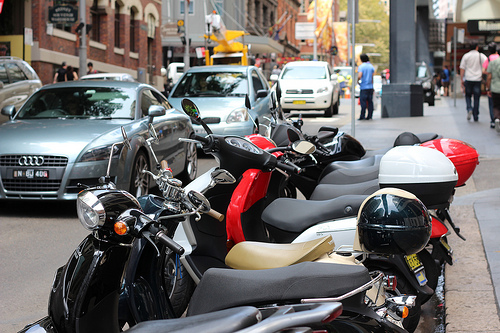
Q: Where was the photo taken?
A: It was taken at the road.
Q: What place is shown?
A: It is a road.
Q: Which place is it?
A: It is a road.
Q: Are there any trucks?
A: No, there are no trucks.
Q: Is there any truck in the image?
A: No, there are no trucks.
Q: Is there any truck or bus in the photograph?
A: No, there are no trucks or buses.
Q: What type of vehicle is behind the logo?
A: The vehicle is a car.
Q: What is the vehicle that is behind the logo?
A: The vehicle is a car.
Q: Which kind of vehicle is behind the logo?
A: The vehicle is a car.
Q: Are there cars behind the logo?
A: Yes, there is a car behind the logo.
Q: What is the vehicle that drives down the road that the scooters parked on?
A: The vehicle is a car.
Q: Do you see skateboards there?
A: No, there are no skateboards.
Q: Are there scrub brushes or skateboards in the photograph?
A: No, there are no skateboards or scrub brushes.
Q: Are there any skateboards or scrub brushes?
A: No, there are no skateboards or scrub brushes.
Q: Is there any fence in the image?
A: No, there are no fences.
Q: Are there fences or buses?
A: No, there are no fences or buses.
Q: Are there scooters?
A: Yes, there are scooters.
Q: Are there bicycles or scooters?
A: Yes, there are scooters.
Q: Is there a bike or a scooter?
A: Yes, there are scooters.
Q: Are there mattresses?
A: No, there are no mattresses.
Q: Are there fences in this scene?
A: No, there are no fences.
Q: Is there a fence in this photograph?
A: No, there are no fences.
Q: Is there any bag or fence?
A: No, there are no fences or bags.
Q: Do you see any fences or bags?
A: No, there are no fences or bags.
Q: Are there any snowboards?
A: No, there are no snowboards.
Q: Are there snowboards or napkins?
A: No, there are no snowboards or napkins.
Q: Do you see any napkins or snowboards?
A: No, there are no snowboards or napkins.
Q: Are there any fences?
A: No, there are no fences.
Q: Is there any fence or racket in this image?
A: No, there are no fences or rackets.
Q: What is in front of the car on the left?
A: The logo is in front of the car.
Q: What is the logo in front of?
A: The logo is in front of the car.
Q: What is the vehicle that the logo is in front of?
A: The vehicle is a car.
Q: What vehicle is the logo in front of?
A: The logo is in front of the car.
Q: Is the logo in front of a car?
A: Yes, the logo is in front of a car.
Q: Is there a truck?
A: No, there are no trucks.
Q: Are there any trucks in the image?
A: No, there are no trucks.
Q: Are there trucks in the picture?
A: No, there are no trucks.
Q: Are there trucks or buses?
A: No, there are no trucks or buses.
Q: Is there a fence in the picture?
A: No, there are no fences.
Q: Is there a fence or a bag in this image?
A: No, there are no fences or bags.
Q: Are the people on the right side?
A: Yes, the people are on the right of the image.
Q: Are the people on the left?
A: No, the people are on the right of the image.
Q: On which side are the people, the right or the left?
A: The people are on the right of the image.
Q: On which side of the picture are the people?
A: The people are on the right of the image.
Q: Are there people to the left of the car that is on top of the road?
A: No, the people are to the right of the car.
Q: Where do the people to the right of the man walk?
A: The people walk on the sidewalk.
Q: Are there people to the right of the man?
A: Yes, there are people to the right of the man.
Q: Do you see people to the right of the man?
A: Yes, there are people to the right of the man.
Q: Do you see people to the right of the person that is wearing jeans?
A: Yes, there are people to the right of the man.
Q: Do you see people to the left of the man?
A: No, the people are to the right of the man.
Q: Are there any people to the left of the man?
A: No, the people are to the right of the man.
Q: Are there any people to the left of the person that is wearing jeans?
A: No, the people are to the right of the man.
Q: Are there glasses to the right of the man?
A: No, there are people to the right of the man.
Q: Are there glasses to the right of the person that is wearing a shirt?
A: No, there are people to the right of the man.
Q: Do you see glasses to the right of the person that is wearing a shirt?
A: No, there are people to the right of the man.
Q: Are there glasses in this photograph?
A: No, there are no glasses.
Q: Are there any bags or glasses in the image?
A: No, there are no glasses or bags.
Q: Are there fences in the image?
A: No, there are no fences.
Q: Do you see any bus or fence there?
A: No, there are no fences or buses.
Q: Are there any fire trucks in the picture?
A: No, there are no fire trucks.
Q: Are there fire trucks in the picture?
A: No, there are no fire trucks.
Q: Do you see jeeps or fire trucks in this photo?
A: No, there are no fire trucks or jeeps.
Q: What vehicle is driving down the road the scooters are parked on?
A: The vehicle is a car.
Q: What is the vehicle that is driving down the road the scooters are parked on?
A: The vehicle is a car.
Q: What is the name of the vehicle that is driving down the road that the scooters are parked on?
A: The vehicle is a car.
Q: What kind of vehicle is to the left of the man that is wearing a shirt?
A: The vehicle is a car.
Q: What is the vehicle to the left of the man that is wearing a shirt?
A: The vehicle is a car.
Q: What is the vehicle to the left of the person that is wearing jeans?
A: The vehicle is a car.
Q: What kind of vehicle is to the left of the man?
A: The vehicle is a car.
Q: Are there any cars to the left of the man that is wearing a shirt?
A: Yes, there is a car to the left of the man.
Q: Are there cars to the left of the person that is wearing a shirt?
A: Yes, there is a car to the left of the man.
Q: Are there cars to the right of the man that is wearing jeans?
A: No, the car is to the left of the man.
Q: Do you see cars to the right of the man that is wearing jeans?
A: No, the car is to the left of the man.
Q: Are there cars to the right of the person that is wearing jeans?
A: No, the car is to the left of the man.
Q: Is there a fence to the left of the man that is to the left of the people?
A: No, there is a car to the left of the man.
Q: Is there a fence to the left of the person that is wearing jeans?
A: No, there is a car to the left of the man.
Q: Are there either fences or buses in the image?
A: No, there are no fences or buses.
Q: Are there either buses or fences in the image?
A: No, there are no fences or buses.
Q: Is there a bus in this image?
A: No, there are no buses.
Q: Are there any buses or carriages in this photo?
A: No, there are no buses or carriages.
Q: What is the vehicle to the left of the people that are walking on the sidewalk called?
A: The vehicle is a car.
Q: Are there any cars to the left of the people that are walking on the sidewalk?
A: Yes, there is a car to the left of the people.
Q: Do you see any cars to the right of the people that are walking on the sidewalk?
A: No, the car is to the left of the people.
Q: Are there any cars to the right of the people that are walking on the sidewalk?
A: No, the car is to the left of the people.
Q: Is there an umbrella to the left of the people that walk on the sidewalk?
A: No, there is a car to the left of the people.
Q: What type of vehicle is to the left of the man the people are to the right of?
A: The vehicle is a car.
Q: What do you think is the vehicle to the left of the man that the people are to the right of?
A: The vehicle is a car.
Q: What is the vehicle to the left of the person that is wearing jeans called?
A: The vehicle is a car.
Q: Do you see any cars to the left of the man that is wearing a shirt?
A: Yes, there is a car to the left of the man.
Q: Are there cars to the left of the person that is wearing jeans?
A: Yes, there is a car to the left of the man.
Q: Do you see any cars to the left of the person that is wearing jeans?
A: Yes, there is a car to the left of the man.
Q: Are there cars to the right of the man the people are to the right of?
A: No, the car is to the left of the man.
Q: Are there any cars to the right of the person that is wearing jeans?
A: No, the car is to the left of the man.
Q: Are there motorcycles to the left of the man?
A: No, there is a car to the left of the man.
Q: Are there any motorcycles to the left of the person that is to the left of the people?
A: No, there is a car to the left of the man.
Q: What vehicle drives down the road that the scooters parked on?
A: The vehicle is a car.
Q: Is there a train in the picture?
A: No, there are no trains.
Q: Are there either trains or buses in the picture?
A: No, there are no trains or buses.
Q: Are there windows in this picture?
A: Yes, there is a window.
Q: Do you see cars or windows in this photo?
A: Yes, there is a window.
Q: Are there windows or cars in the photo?
A: Yes, there is a window.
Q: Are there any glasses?
A: No, there are no glasses.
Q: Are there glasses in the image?
A: No, there are no glasses.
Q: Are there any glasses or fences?
A: No, there are no glasses or fences.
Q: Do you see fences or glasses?
A: No, there are no glasses or fences.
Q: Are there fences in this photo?
A: No, there are no fences.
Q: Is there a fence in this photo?
A: No, there are no fences.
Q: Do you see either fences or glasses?
A: No, there are no fences or glasses.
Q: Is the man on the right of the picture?
A: Yes, the man is on the right of the image.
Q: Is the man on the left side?
A: No, the man is on the right of the image.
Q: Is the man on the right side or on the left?
A: The man is on the right of the image.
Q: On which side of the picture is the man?
A: The man is on the right of the image.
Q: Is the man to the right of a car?
A: Yes, the man is to the right of a car.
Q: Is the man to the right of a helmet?
A: No, the man is to the right of a car.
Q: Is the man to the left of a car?
A: No, the man is to the right of a car.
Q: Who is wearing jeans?
A: The man is wearing jeans.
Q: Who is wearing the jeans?
A: The man is wearing jeans.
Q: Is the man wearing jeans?
A: Yes, the man is wearing jeans.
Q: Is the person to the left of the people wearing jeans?
A: Yes, the man is wearing jeans.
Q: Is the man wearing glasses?
A: No, the man is wearing jeans.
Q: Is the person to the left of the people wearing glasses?
A: No, the man is wearing jeans.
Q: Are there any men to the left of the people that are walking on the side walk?
A: Yes, there is a man to the left of the people.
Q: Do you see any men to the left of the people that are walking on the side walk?
A: Yes, there is a man to the left of the people.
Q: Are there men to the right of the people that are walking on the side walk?
A: No, the man is to the left of the people.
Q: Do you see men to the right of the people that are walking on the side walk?
A: No, the man is to the left of the people.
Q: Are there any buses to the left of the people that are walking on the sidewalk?
A: No, there is a man to the left of the people.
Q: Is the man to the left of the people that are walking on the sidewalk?
A: Yes, the man is to the left of the people.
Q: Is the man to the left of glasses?
A: No, the man is to the left of the people.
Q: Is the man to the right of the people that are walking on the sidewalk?
A: No, the man is to the left of the people.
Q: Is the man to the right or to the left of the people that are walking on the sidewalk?
A: The man is to the left of the people.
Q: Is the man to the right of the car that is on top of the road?
A: Yes, the man is to the right of the car.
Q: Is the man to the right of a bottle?
A: No, the man is to the right of the car.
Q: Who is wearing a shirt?
A: The man is wearing a shirt.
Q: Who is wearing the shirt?
A: The man is wearing a shirt.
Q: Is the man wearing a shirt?
A: Yes, the man is wearing a shirt.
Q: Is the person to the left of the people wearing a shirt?
A: Yes, the man is wearing a shirt.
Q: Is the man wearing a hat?
A: No, the man is wearing a shirt.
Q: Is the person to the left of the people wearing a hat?
A: No, the man is wearing a shirt.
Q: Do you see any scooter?
A: Yes, there is a scooter.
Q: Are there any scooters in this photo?
A: Yes, there is a scooter.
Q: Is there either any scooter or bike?
A: Yes, there is a scooter.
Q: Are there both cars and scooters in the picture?
A: Yes, there are both a scooter and a car.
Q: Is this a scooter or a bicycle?
A: This is a scooter.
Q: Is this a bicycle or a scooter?
A: This is a scooter.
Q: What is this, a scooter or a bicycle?
A: This is a scooter.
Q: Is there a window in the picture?
A: Yes, there is a window.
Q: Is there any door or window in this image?
A: Yes, there is a window.